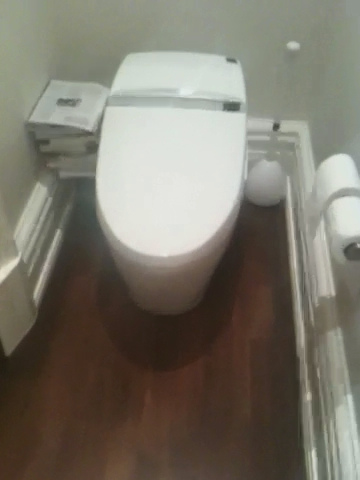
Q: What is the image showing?
A: It is showing a bathroom.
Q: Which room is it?
A: It is a bathroom.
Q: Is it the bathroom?
A: Yes, it is the bathroom.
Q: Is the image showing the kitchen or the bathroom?
A: It is showing the bathroom.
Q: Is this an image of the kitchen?
A: No, the picture is showing the bathroom.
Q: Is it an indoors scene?
A: Yes, it is indoors.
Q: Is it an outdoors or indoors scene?
A: It is indoors.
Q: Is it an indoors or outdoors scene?
A: It is indoors.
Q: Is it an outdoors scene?
A: No, it is indoors.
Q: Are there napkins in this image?
A: No, there are no napkins.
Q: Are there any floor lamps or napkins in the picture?
A: No, there are no napkins or floor lamps.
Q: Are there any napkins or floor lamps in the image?
A: No, there are no napkins or floor lamps.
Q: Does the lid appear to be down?
A: Yes, the lid is down.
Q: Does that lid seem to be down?
A: Yes, the lid is down.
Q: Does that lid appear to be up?
A: No, the lid is down.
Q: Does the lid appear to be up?
A: No, the lid is down.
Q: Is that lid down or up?
A: The lid is down.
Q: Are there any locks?
A: No, there are no locks.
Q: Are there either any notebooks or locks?
A: No, there are no locks or notebooks.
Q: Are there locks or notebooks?
A: No, there are no locks or notebooks.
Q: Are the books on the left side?
A: Yes, the books are on the left of the image.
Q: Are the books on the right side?
A: No, the books are on the left of the image.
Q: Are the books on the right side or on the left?
A: The books are on the left of the image.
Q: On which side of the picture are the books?
A: The books are on the left of the image.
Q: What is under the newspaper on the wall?
A: The books are under the newspaper.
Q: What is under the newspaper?
A: The books are under the newspaper.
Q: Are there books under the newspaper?
A: Yes, there are books under the newspaper.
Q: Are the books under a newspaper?
A: Yes, the books are under a newspaper.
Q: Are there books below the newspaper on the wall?
A: Yes, there are books below the newspaper.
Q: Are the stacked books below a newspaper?
A: Yes, the books are below a newspaper.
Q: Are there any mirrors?
A: No, there are no mirrors.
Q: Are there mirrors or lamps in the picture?
A: No, there are no mirrors or lamps.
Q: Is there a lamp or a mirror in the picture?
A: No, there are no mirrors or lamps.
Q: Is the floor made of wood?
A: Yes, the floor is made of wood.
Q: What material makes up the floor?
A: The floor is made of wood.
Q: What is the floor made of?
A: The floor is made of wood.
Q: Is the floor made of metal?
A: No, the floor is made of wood.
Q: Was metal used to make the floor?
A: No, the floor is made of wood.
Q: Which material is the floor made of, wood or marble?
A: The floor is made of wood.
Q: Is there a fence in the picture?
A: No, there are no fences.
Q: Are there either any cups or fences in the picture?
A: No, there are no fences or cups.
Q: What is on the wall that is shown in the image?
A: The newspaper is on the wall.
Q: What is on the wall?
A: The newspaper is on the wall.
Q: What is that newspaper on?
A: The newspaper is on the wall.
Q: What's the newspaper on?
A: The newspaper is on the wall.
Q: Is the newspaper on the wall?
A: Yes, the newspaper is on the wall.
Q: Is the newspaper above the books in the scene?
A: Yes, the newspaper is above the books.